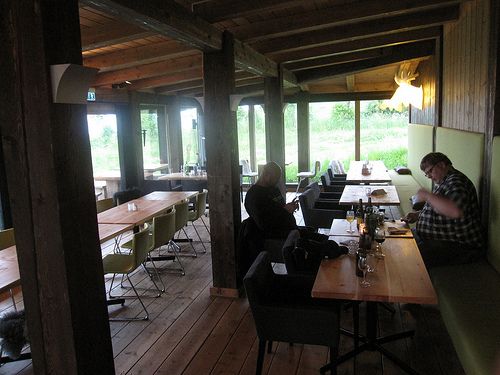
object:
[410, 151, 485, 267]
man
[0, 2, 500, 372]
eating area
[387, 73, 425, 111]
light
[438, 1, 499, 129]
wall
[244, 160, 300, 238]
man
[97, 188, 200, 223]
table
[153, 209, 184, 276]
chairs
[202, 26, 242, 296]
posts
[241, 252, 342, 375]
chair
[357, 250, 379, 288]
glasses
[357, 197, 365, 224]
wine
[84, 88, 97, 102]
sign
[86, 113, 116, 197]
exit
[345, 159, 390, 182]
table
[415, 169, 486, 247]
checkered shirt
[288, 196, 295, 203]
phone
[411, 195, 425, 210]
drink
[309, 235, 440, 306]
table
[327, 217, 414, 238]
table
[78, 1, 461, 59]
rafters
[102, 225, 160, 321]
empty chair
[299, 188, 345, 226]
chair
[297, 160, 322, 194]
chair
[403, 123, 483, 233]
headboards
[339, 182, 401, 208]
table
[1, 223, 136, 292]
table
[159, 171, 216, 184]
table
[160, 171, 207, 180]
wood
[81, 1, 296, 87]
beams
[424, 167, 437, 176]
glasses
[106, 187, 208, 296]
row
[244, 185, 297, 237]
black shirt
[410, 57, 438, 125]
paneling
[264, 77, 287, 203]
posts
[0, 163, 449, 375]
patio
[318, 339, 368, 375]
legs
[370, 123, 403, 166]
grass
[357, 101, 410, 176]
window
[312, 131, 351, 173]
grass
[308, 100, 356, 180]
window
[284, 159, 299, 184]
grass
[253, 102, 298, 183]
window